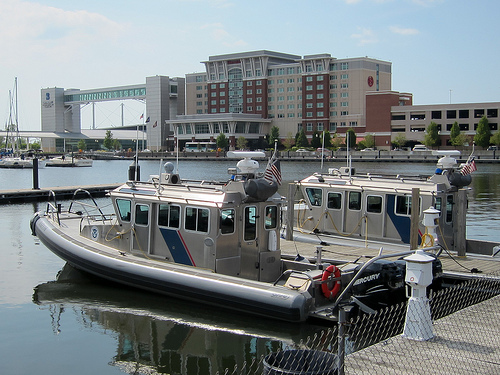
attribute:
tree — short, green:
[465, 109, 494, 160]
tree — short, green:
[213, 127, 229, 152]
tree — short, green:
[265, 127, 282, 146]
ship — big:
[276, 167, 472, 264]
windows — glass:
[207, 86, 267, 95]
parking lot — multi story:
[293, 140, 423, 165]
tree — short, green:
[213, 131, 230, 151]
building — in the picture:
[144, 45, 414, 147]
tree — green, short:
[349, 126, 370, 150]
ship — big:
[37, 165, 436, 312]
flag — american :
[258, 148, 288, 189]